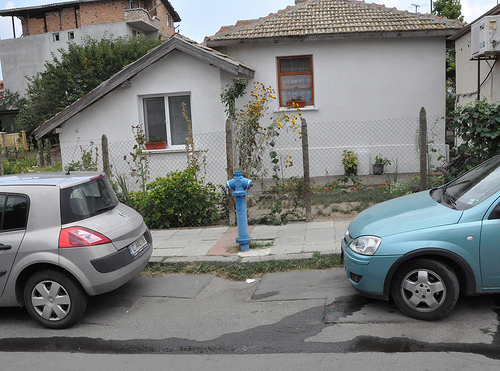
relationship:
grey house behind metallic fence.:
[34, 0, 469, 201] [49, 121, 496, 212]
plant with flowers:
[214, 72, 304, 177] [242, 79, 304, 141]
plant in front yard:
[214, 72, 304, 177] [62, 75, 447, 224]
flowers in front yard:
[242, 79, 304, 141] [62, 75, 447, 224]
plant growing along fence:
[444, 103, 495, 170] [441, 66, 499, 160]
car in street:
[1, 169, 150, 321] [0, 265, 498, 370]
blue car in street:
[338, 156, 499, 320] [0, 265, 498, 370]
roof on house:
[32, 0, 466, 144] [199, 2, 466, 182]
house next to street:
[199, 2, 466, 182] [0, 265, 498, 370]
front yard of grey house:
[113, 158, 444, 229] [34, 29, 254, 222]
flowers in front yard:
[242, 101, 323, 159] [113, 158, 444, 229]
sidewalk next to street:
[145, 212, 365, 267] [0, 265, 498, 370]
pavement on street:
[121, 276, 335, 368] [0, 255, 494, 368]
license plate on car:
[127, 235, 148, 258] [2, 168, 155, 333]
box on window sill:
[141, 139, 170, 156] [139, 146, 194, 154]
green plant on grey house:
[341, 148, 357, 172] [34, 29, 254, 222]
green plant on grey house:
[375, 153, 391, 166] [34, 29, 254, 222]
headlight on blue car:
[347, 234, 380, 257] [338, 156, 499, 320]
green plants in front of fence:
[138, 161, 223, 228] [2, 114, 497, 215]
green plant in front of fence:
[340, 147, 357, 172] [2, 114, 497, 215]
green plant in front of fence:
[371, 151, 388, 173] [2, 114, 497, 215]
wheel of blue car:
[383, 245, 468, 319] [338, 156, 499, 320]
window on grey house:
[275, 52, 315, 107] [34, 29, 254, 222]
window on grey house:
[139, 90, 193, 147] [34, 29, 254, 222]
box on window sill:
[145, 142, 166, 150] [138, 144, 204, 154]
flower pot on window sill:
[280, 95, 310, 108] [268, 104, 315, 114]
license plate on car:
[125, 235, 150, 255] [1, 169, 150, 321]